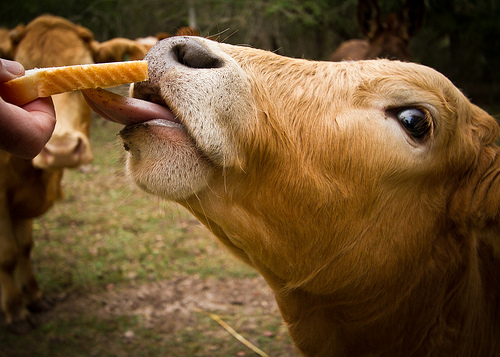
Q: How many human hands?
A: One.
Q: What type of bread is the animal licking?
A: Sliced.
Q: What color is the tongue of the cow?
A: Pink.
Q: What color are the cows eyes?
A: Brown.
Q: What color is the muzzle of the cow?
A: Cream.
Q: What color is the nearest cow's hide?
A: Yellow.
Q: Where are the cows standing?
A: On dirt and grass.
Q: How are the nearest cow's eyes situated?
A: Open.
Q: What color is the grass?
A: Green and brown.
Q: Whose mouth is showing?
A: The cow.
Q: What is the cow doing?
A: Eating.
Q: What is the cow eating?
A: Bread.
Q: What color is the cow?
A: Brown.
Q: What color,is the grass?
A: Green.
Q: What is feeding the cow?
A: A hand.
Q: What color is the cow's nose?
A: Black.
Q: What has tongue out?
A: The cow.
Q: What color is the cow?
A: Brown.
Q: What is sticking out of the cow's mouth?
A: A tongue.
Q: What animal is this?
A: A cow.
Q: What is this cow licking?
A: A piece of bread.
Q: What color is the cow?
A: Brown.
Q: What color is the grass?
A: Green.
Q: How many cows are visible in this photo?
A: Two.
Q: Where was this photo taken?
A: At an animal exhibit.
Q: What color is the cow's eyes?
A: Black.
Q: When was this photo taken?
A: Outside, during the daytime.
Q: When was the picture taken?
A: Day time.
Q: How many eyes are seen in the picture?
A: One.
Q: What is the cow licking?
A: A slice of bread.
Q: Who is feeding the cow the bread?
A: A human.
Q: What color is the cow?
A: Brown.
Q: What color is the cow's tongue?
A: Pink.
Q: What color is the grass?
A: Green.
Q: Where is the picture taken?
A: A farm.